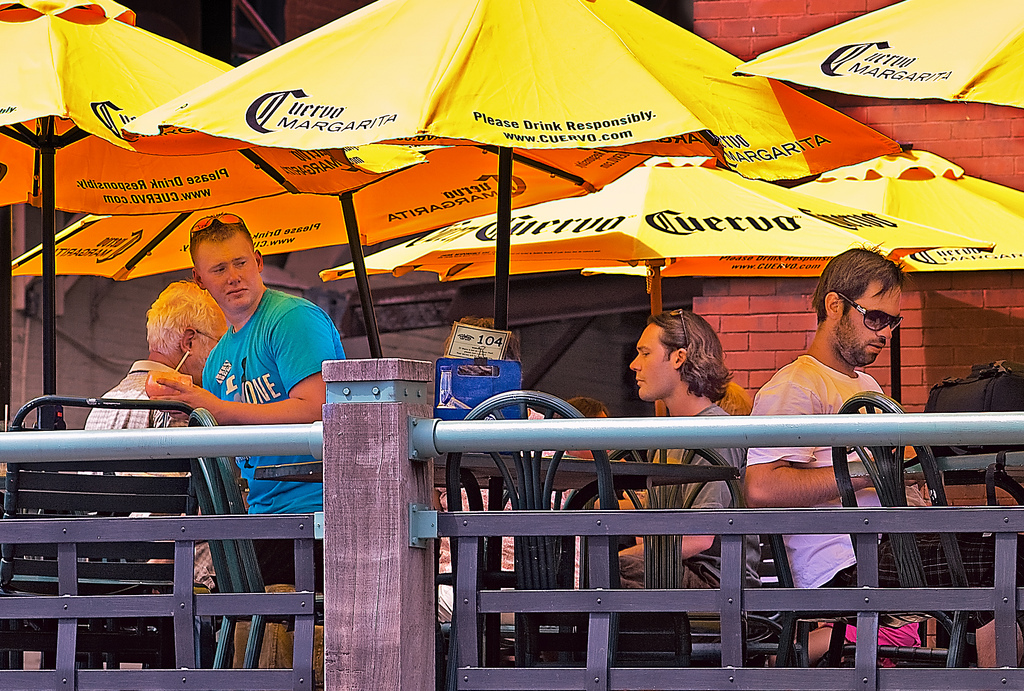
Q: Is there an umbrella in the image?
A: Yes, there are umbrellas.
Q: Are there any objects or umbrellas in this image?
A: Yes, there are umbrellas.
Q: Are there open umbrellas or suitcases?
A: Yes, there are open umbrellas.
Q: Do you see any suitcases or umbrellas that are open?
A: Yes, the umbrellas are open.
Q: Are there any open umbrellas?
A: Yes, there are open umbrellas.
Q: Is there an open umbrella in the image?
A: Yes, there are open umbrellas.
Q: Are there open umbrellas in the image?
A: Yes, there are open umbrellas.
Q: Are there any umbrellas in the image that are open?
A: Yes, there are umbrellas that are open.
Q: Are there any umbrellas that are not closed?
A: Yes, there are open umbrellas.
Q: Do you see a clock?
A: No, there are no clocks.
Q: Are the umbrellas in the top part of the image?
A: Yes, the umbrellas are in the top of the image.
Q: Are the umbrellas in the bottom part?
A: No, the umbrellas are in the top of the image.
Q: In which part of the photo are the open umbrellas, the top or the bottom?
A: The umbrellas are in the top of the image.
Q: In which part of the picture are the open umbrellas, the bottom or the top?
A: The umbrellas are in the top of the image.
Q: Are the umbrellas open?
A: Yes, the umbrellas are open.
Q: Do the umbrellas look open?
A: Yes, the umbrellas are open.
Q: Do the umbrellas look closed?
A: No, the umbrellas are open.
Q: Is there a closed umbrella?
A: No, there are umbrellas but they are open.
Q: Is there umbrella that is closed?
A: No, there are umbrellas but they are open.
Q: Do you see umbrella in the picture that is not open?
A: No, there are umbrellas but they are open.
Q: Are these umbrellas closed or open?
A: The umbrellas are open.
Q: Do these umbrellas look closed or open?
A: The umbrellas are open.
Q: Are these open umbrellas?
A: Yes, these are open umbrellas.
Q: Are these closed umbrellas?
A: No, these are open umbrellas.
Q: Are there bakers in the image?
A: No, there are no bakers.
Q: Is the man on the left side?
A: Yes, the man is on the left of the image.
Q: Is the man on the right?
A: No, the man is on the left of the image.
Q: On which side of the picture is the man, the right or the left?
A: The man is on the left of the image.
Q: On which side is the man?
A: The man is on the left of the image.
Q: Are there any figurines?
A: No, there are no figurines.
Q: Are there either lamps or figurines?
A: No, there are no figurines or lamps.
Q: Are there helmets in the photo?
A: No, there are no helmets.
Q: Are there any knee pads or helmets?
A: No, there are no helmets or knee pads.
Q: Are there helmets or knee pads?
A: No, there are no helmets or knee pads.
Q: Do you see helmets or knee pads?
A: No, there are no helmets or knee pads.